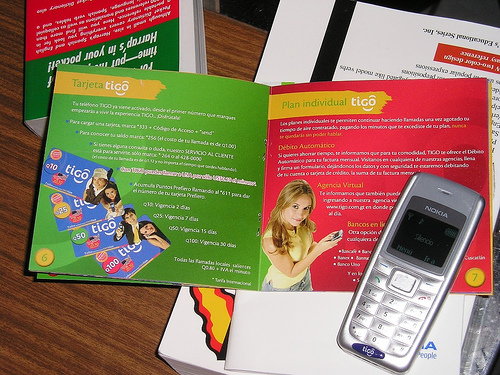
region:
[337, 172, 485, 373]
a silver Nokia cellphone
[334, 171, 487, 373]
a gray Nokia mobile phone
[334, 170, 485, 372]
a gray mobile phone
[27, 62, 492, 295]
a tigo individual cellphone plan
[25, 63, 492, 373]
a tigo plan for Nokia mobile phone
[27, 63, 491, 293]
a Nokia individual phone plan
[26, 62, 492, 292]
a booklet about tigo cellphone plans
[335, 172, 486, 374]
a cellphone with a tigo plan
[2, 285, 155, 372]
a brown wood table top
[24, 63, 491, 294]
pages 6 and 7 of the tigo booklet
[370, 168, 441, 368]
phone on the desk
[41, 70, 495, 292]
the book is open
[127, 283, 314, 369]
paper on the desk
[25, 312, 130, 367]
the desk is wood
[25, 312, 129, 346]
the desk is brown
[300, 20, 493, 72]
book on the desk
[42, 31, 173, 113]
book on the desk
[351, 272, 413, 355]
buttons on the phone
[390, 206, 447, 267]
screen of the phone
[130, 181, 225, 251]
writing in the book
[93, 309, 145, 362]
DESK MADE OUT OF WOOD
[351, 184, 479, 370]
PHONE ON TOP OF BOOK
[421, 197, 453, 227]
NOKIA ON THE PHONE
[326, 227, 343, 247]
WOMAN HOLDING A PHONE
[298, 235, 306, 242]
WOMAN HAS ON A YELLOW SHIRT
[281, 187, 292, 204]
LADY HAS LONG BLOND HAIR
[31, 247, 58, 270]
BOOK OPEN TO PAGE 6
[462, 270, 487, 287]
BOOK OPEN TO PAGE 7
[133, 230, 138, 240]
MAN HAS ON A TIE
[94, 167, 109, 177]
MAN WEARING A TAN HAT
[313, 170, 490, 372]
cell phone laying on the table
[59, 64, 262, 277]
help page is in a different language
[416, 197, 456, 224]
name brand of the phone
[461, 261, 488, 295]
page seven of the booklet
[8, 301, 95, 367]
wooden table top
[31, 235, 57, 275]
page six of the booklet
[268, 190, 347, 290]
picture of a woman holding a phone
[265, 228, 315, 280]
woman is wearing a yellow shirt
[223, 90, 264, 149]
page is green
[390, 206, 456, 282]
phone is turned on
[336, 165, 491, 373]
a cellphone sitting on the pepers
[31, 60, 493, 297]
the open book sitting on the table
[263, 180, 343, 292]
the woman holding the cellphone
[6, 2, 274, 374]
the table the books are sitting on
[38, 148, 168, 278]
the different cards in the book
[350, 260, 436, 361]
the buttons on the book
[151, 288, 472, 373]
some more books in the pile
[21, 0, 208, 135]
another book sitting on the side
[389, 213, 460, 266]
the screen on the phone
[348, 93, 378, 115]
the name of the phone